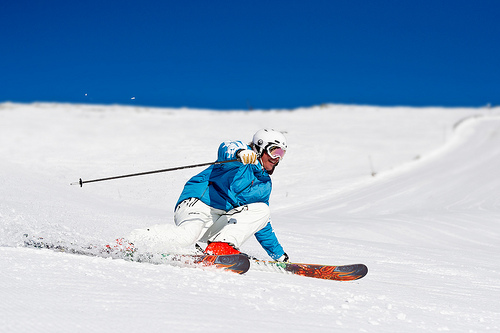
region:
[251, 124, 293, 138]
Helmet on person's head.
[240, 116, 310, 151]
Person wearing white helmet.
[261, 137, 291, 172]
Goggles on person's face.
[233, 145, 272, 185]
Person wearing white glove.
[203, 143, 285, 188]
Person holding ski pole.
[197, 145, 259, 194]
Person wearing blue jacket.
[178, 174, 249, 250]
Person wearing white pants.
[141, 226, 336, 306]
Person has skis on feet.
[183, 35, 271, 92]
Sky is blue and clear.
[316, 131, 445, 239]
Ground is covered in snow.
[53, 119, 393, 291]
A man skiing down a slope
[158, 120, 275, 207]
A bright blue ski jacket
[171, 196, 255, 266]
Pair of white snow pants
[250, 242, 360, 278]
An orange, blue and grey ski on right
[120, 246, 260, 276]
An orange, blue and grey ski on left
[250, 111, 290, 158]
A white helmet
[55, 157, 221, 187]
A black ski pole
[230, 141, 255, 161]
A white ski glove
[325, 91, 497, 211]
Marks in the snow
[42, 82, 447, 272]
A slope of snow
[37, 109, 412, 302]
person who is skiing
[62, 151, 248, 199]
ski pole is in the air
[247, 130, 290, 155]
white helmet on the head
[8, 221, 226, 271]
snow being kicked up from the ski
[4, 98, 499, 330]
bright white snow on the ground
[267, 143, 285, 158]
goggles that are tinted pink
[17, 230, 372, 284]
skis are on their sides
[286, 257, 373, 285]
bottom of the ski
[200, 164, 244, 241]
shadow on the body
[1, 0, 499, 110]
dark blue sky with no clouds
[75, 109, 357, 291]
skier on hill side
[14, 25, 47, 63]
blue sky with no clouds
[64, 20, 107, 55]
blue sky with no clouds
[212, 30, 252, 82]
blue sky with no clouds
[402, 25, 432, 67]
blue sky with no clouds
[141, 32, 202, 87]
blue sky with no clouds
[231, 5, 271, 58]
blue sky with no clouds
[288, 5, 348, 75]
blue sky with no clouds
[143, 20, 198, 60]
blue sky with no clouds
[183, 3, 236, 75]
blue sky with no clouds